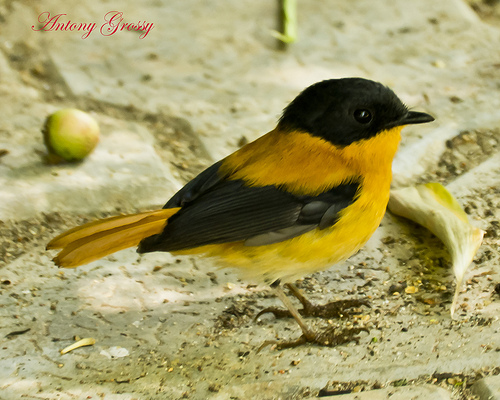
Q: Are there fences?
A: No, there are no fences.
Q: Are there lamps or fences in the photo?
A: No, there are no fences or lamps.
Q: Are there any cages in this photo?
A: No, there are no cages.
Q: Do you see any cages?
A: No, there are no cages.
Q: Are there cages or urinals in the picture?
A: No, there are no cages or urinals.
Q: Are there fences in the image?
A: No, there are no fences.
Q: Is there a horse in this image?
A: No, there are no horses.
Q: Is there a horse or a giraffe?
A: No, there are no horses or giraffes.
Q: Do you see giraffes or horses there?
A: No, there are no horses or giraffes.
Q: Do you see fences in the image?
A: No, there are no fences.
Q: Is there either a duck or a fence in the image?
A: No, there are no fences or ducks.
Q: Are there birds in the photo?
A: Yes, there is a bird.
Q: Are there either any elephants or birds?
A: Yes, there is a bird.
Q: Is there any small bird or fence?
A: Yes, there is a small bird.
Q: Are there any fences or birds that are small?
A: Yes, the bird is small.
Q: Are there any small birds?
A: Yes, there is a small bird.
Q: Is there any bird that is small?
A: Yes, there is a bird that is small.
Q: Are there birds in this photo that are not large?
A: Yes, there is a small bird.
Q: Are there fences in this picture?
A: No, there are no fences.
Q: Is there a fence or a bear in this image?
A: No, there are no fences or bears.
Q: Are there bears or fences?
A: No, there are no fences or bears.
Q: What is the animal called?
A: The animal is a bird.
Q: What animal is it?
A: The animal is a bird.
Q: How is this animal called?
A: That is a bird.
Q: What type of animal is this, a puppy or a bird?
A: That is a bird.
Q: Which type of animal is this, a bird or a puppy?
A: That is a bird.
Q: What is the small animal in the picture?
A: The animal is a bird.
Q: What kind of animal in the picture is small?
A: The animal is a bird.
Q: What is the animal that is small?
A: The animal is a bird.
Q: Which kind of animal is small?
A: The animal is a bird.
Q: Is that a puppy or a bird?
A: That is a bird.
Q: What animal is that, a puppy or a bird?
A: That is a bird.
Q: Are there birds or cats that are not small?
A: No, there is a bird but it is small.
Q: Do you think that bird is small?
A: Yes, the bird is small.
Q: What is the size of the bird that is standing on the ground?
A: The bird is small.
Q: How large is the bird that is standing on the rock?
A: The bird is small.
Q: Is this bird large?
A: No, the bird is small.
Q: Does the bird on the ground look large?
A: No, the bird is small.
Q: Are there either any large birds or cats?
A: No, there is a bird but it is small.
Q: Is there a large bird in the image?
A: No, there is a bird but it is small.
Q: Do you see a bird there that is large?
A: No, there is a bird but it is small.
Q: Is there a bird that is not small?
A: No, there is a bird but it is small.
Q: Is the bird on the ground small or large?
A: The bird is small.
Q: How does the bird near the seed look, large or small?
A: The bird is small.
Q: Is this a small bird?
A: Yes, this is a small bird.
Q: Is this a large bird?
A: No, this is a small bird.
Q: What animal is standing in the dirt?
A: The bird is standing in the dirt.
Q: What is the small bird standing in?
A: The bird is standing in the dirt.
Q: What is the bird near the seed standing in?
A: The bird is standing in the dirt.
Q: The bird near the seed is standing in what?
A: The bird is standing in the dirt.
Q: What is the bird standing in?
A: The bird is standing in the dirt.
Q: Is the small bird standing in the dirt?
A: Yes, the bird is standing in the dirt.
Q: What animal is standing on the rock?
A: The animal is a bird.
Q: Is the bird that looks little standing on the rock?
A: Yes, the bird is standing on the rock.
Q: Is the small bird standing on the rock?
A: Yes, the bird is standing on the rock.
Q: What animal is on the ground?
A: The bird is on the ground.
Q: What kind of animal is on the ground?
A: The animal is a bird.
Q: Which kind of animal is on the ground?
A: The animal is a bird.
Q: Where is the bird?
A: The bird is on the ground.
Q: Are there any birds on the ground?
A: Yes, there is a bird on the ground.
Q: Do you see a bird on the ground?
A: Yes, there is a bird on the ground.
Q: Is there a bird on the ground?
A: Yes, there is a bird on the ground.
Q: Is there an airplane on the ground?
A: No, there is a bird on the ground.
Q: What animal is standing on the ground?
A: The bird is standing on the ground.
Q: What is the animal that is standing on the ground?
A: The animal is a bird.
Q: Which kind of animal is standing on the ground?
A: The animal is a bird.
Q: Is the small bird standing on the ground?
A: Yes, the bird is standing on the ground.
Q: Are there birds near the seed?
A: Yes, there is a bird near the seed.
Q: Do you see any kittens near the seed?
A: No, there is a bird near the seed.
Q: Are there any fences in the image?
A: No, there are no fences.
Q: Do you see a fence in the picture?
A: No, there are no fences.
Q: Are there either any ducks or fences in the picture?
A: No, there are no fences or ducks.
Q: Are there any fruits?
A: Yes, there is a fruit.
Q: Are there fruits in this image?
A: Yes, there is a fruit.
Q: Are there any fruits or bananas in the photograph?
A: Yes, there is a fruit.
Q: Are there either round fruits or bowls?
A: Yes, there is a round fruit.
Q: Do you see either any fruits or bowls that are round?
A: Yes, the fruit is round.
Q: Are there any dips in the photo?
A: No, there are no dips.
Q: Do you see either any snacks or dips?
A: No, there are no dips or snacks.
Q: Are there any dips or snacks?
A: No, there are no dips or snacks.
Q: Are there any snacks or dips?
A: No, there are no dips or snacks.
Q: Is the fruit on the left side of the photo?
A: Yes, the fruit is on the left of the image.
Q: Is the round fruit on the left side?
A: Yes, the fruit is on the left of the image.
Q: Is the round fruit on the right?
A: No, the fruit is on the left of the image.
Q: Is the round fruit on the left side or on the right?
A: The fruit is on the left of the image.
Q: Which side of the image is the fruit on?
A: The fruit is on the left of the image.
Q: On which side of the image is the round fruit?
A: The fruit is on the left of the image.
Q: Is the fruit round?
A: Yes, the fruit is round.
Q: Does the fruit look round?
A: Yes, the fruit is round.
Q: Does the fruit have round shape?
A: Yes, the fruit is round.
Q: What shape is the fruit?
A: The fruit is round.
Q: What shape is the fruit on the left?
A: The fruit is round.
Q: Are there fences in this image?
A: No, there are no fences.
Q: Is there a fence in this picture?
A: No, there are no fences.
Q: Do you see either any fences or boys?
A: No, there are no fences or boys.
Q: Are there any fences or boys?
A: No, there are no fences or boys.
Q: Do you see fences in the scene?
A: No, there are no fences.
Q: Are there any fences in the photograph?
A: No, there are no fences.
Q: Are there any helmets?
A: No, there are no helmets.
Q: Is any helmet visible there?
A: No, there are no helmets.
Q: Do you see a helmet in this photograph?
A: No, there are no helmets.